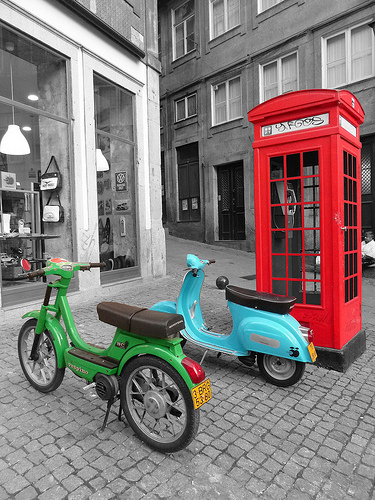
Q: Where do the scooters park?
A: On a cobblestone street.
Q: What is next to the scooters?
A: A red telephone booth.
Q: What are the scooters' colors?
A: Blue and green.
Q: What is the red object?
A: Phone booth.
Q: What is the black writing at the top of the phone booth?
A: Graffiti.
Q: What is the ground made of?
A: Brick pavement.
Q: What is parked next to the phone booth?
A: Two scooters.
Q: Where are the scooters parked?
A: On brick pavement.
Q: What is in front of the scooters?
A: Storefront windows.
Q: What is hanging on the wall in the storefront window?
A: Two pocketbooks.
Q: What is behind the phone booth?
A: Tall stone buildings.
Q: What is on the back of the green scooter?
A: Yellow license plate.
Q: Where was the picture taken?
A: Storefront.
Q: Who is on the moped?
A: Nobody.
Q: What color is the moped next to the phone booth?
A: Blue.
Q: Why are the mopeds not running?
A: Off.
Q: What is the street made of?
A: Stone.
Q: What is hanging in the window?
A: Purses.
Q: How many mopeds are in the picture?
A: 2.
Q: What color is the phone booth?
A: Red.